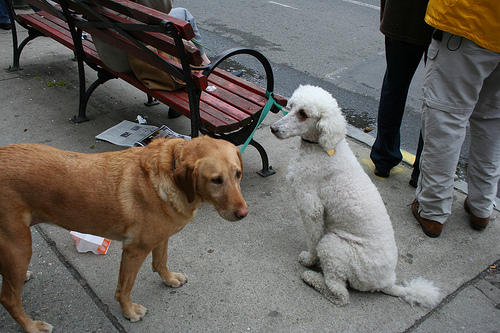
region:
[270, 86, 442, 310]
a poodle sitting on a sidewalk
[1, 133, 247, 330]
a golden retriever standing on a sidewalk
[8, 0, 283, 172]
a black bench with red wooden seat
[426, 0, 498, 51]
a yellow windbreaker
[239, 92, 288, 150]
a green leach attached to a bench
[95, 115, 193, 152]
a magazine on a sidewalk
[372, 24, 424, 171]
a person wearing blue jeans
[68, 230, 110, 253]
a white and orange paper littered on the ground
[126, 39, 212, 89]
a bag on a bench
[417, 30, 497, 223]
a man wearing gray pants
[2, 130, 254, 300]
Brown dog standing on the side walk.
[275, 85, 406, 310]
White poodle standing on the side walk.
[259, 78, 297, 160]
Green leash holding down dogs.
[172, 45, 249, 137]
Red and black bench on the side walk.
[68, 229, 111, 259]
Orange and white bag on the ground.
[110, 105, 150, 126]
Small piece of white trash on the ground.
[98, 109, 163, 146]
Magazine on the ground.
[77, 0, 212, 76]
Person sitting on the bench.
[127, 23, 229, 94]
Brown bag on top of bench.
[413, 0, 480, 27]
Yellow jacket on man's body.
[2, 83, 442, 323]
two dogs on sidewalk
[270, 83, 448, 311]
white dog on sidewalk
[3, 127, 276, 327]
brown dog on sidewalk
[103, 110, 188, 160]
periodical on the sidewalk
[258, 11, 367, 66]
street area where vehicles travel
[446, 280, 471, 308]
crack in the sidewalk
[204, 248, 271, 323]
sidewalk with dogs and people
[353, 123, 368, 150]
curb of the sidewalk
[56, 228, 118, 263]
packaging on the ground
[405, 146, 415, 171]
yellow streak on curb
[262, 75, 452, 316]
a white poodle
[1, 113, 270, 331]
a brown dog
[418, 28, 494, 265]
a person wearing cargo pants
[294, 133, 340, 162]
a collar on the dog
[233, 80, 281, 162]
a green leash tied to the bench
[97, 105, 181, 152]
a magazine under the bench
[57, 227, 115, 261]
trash that is on the ground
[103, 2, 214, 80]
a person sitting on the bench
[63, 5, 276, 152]
a bench on the sidewalk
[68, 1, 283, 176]
a bench that is bolted down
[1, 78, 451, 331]
dogs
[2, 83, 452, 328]
two dogs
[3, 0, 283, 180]
the bench is red painted wood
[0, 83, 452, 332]
one dog is white and one is tan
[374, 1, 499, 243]
two people stand on the sidewalk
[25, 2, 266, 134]
people sit on the bench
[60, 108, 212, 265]
papers are on the ground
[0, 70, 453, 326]
the dogs are tied to the bench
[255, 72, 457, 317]
the white dog is sitting